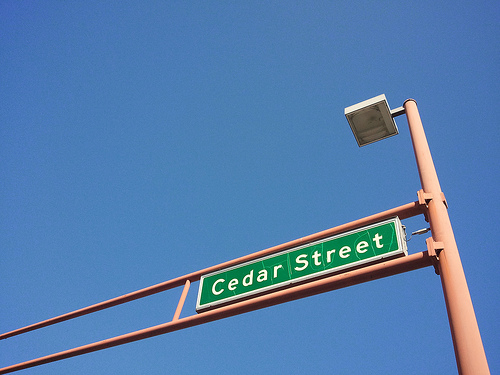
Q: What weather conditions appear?
A: It is clear.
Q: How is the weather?
A: It is clear.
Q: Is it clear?
A: Yes, it is clear.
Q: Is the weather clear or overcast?
A: It is clear.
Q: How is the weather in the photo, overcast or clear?
A: It is clear.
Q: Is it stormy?
A: No, it is clear.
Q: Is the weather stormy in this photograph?
A: No, it is clear.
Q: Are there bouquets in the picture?
A: No, there are no bouquets.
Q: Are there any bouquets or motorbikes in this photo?
A: No, there are no bouquets or motorbikes.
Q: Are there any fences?
A: No, there are no fences.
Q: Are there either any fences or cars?
A: No, there are no fences or cars.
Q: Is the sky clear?
A: Yes, the sky is clear.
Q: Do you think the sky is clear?
A: Yes, the sky is clear.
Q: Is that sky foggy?
A: No, the sky is clear.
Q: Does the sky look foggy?
A: No, the sky is clear.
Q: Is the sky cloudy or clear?
A: The sky is clear.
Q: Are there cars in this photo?
A: No, there are no cars.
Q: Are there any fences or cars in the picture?
A: No, there are no cars or fences.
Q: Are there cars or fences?
A: No, there are no cars or fences.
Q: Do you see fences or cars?
A: No, there are no cars or fences.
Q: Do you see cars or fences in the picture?
A: No, there are no cars or fences.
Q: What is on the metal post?
A: The sign is on the post.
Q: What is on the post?
A: The sign is on the post.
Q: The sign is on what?
A: The sign is on the post.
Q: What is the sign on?
A: The sign is on the post.